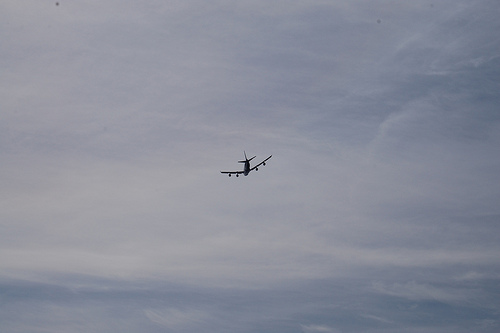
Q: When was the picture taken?
A: Daytime.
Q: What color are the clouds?
A: White.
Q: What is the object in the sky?
A: An airplane.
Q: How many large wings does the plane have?
A: Two.